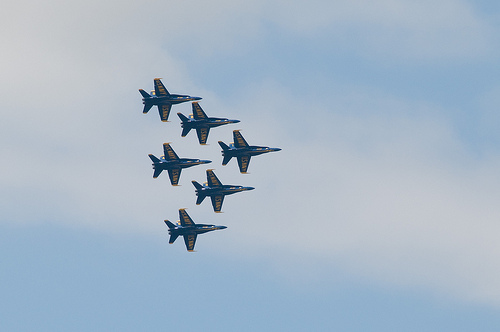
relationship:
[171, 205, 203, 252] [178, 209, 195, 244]
wings are "us navy"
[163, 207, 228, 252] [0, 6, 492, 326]
jet are flying in sky